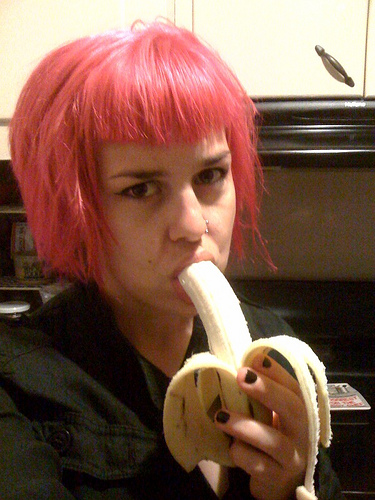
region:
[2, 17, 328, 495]
a person eating banana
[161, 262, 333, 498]
a banana the person is eating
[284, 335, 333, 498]
a part of the peelings of the banana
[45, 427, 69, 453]
a button of the person's shirt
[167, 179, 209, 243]
a nose of the person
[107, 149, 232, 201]
eyes and eyebrow of the person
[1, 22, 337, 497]
a person wearing green top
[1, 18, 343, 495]
a person with a weird looking hair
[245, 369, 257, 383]
a painted nail of the person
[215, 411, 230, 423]
a painted nail of the person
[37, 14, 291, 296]
girl has pink hair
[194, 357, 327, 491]
girl is holding a banana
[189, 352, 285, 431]
fingernails are painted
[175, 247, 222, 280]
girl taking a bite out of banana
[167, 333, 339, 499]
banana has been peeled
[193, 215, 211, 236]
girl has nose piercing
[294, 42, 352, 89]
cabinet handle is silver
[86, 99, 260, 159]
girl has bangs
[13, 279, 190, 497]
shirt is black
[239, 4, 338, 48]
kitchen cabinet is white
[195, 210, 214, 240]
silver nose piercing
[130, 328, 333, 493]
the yellow banana peel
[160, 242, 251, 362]
the white inner part of the banana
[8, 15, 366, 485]
a girl eating a banana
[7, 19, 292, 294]
the girl's pink hair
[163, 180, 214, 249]
the girl's nose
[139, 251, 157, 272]
the birthmark on the right of her face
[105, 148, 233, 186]
brown hairy eyebrows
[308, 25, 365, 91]
the cabinet handle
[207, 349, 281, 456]
black painted fingernails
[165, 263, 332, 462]
A half eaten banana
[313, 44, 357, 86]
A cabinet door handle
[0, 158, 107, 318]
Shelves with food items inside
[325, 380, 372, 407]
A small square painted object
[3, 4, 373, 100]
White kitchen cabinets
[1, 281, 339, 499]
A dark black shirt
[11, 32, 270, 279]
Short bright red hair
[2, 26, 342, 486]
A young woman with short red hair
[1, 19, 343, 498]
A young lady eating a banana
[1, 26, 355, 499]
A young lady in a black shirt eating a piece of fruit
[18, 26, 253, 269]
this is a lady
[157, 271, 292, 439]
she is eating a banana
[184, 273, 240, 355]
the banana is ripe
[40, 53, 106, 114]
the hair is red in color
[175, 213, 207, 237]
this is the nose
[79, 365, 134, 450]
the jacket is black in color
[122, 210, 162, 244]
the lady is light skinned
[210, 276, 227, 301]
the banana is yellow in color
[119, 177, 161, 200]
this is the eye